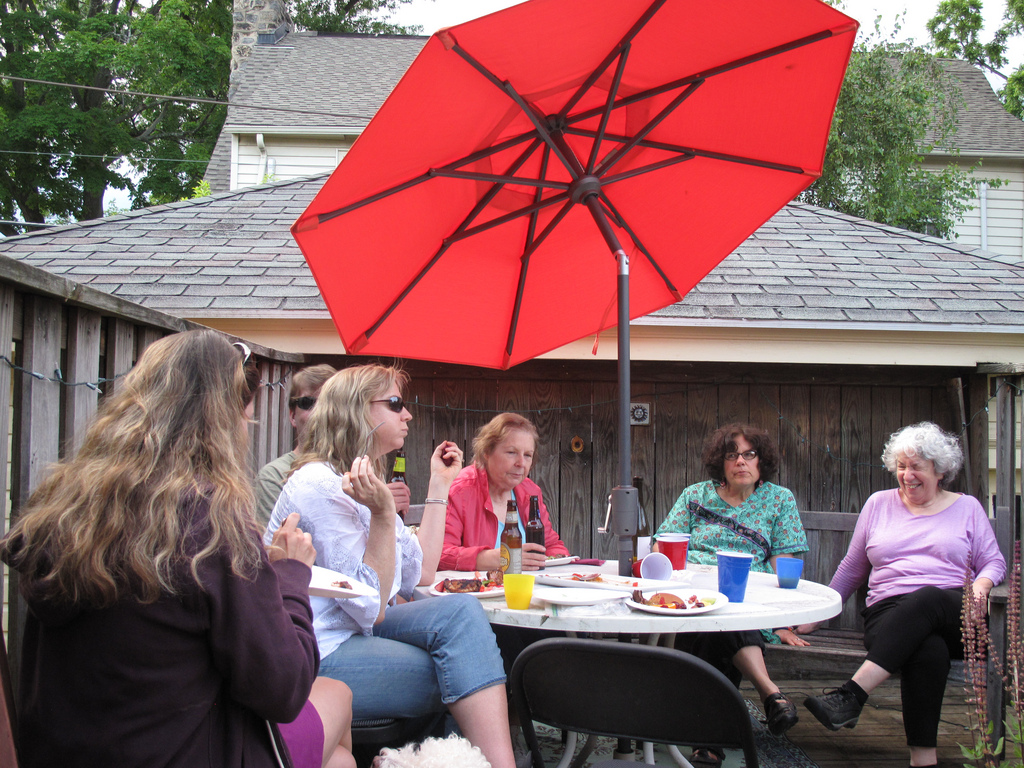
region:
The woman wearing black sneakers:
[791, 412, 1007, 764]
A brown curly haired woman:
[663, 428, 825, 742]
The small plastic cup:
[769, 551, 818, 593]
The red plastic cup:
[655, 531, 694, 567]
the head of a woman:
[331, 353, 462, 478]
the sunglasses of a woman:
[370, 390, 422, 429]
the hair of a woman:
[296, 340, 418, 497]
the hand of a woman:
[287, 453, 453, 610]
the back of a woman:
[47, 328, 260, 554]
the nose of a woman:
[874, 454, 958, 511]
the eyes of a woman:
[874, 457, 950, 511]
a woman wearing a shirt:
[822, 467, 1022, 651]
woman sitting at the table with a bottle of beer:
[468, 399, 561, 561]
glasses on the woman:
[686, 420, 779, 501]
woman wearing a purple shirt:
[866, 404, 993, 633]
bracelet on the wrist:
[419, 497, 446, 513]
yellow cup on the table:
[501, 576, 537, 612]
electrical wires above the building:
[77, 72, 229, 190]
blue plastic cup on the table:
[715, 540, 754, 605]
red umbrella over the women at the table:
[276, 0, 900, 371]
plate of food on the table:
[634, 579, 718, 619]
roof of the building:
[807, 236, 918, 317]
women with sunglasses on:
[267, 346, 473, 613]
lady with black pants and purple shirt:
[820, 417, 1016, 760]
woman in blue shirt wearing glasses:
[656, 390, 827, 580]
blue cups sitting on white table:
[703, 514, 847, 629]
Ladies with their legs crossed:
[8, 337, 517, 765]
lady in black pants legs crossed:
[834, 417, 1006, 762]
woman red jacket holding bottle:
[432, 410, 573, 572]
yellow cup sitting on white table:
[474, 570, 561, 646]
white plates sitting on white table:
[540, 552, 733, 635]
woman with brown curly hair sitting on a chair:
[652, 421, 809, 767]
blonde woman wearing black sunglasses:
[264, 362, 517, 767]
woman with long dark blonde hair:
[2, 333, 358, 764]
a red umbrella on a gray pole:
[291, 2, 861, 575]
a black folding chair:
[513, 636, 760, 767]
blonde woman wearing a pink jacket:
[438, 410, 569, 572]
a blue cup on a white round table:
[408, 555, 842, 632]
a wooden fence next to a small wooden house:
[0, 163, 1021, 654]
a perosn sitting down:
[681, 417, 815, 580]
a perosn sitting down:
[260, 335, 458, 648]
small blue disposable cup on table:
[712, 547, 745, 598]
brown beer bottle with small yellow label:
[386, 447, 406, 517]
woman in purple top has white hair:
[798, 422, 1001, 764]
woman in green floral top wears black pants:
[650, 422, 810, 764]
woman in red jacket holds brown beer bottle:
[430, 409, 567, 572]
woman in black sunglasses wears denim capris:
[261, 365, 511, 764]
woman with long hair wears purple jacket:
[1, 330, 353, 764]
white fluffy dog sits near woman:
[368, 729, 483, 764]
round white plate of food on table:
[618, 579, 727, 615]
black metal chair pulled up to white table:
[509, 633, 760, 767]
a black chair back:
[510, 634, 768, 762]